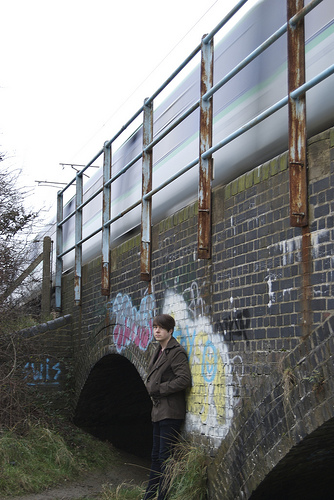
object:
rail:
[55, 190, 63, 312]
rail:
[74, 170, 83, 306]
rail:
[102, 140, 112, 295]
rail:
[141, 97, 154, 282]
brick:
[221, 238, 287, 341]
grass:
[0, 380, 117, 494]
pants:
[142, 419, 179, 500]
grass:
[36, 428, 63, 459]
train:
[0, 0, 334, 307]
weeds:
[72, 440, 94, 457]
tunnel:
[72, 353, 152, 465]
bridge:
[0, 126, 334, 500]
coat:
[144, 336, 190, 423]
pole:
[286, 0, 306, 227]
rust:
[289, 31, 295, 86]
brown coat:
[145, 335, 192, 423]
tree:
[0, 150, 50, 423]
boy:
[141, 314, 191, 500]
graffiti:
[105, 281, 243, 455]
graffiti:
[23, 358, 61, 385]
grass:
[151, 432, 208, 500]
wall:
[0, 126, 334, 500]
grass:
[0, 458, 13, 499]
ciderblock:
[230, 208, 259, 226]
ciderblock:
[270, 316, 276, 326]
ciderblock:
[263, 316, 269, 327]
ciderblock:
[284, 314, 292, 324]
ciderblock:
[250, 319, 258, 327]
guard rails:
[55, 0, 334, 313]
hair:
[153, 314, 175, 333]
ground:
[1, 471, 115, 497]